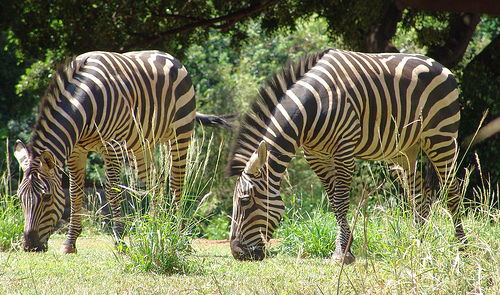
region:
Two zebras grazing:
[23, 75, 454, 256]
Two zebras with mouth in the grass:
[17, 87, 382, 263]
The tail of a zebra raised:
[207, 115, 226, 125]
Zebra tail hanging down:
[426, 170, 435, 187]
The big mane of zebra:
[251, 104, 267, 124]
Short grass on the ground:
[52, 275, 86, 293]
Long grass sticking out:
[140, 230, 173, 269]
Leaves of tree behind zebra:
[72, 22, 124, 46]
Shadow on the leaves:
[472, 71, 497, 103]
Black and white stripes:
[51, 109, 83, 114]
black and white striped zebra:
[7, 35, 201, 245]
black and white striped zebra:
[212, 38, 467, 254]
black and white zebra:
[226, 34, 478, 267]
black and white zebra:
[12, 41, 209, 254]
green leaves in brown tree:
[234, 30, 279, 61]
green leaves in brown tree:
[39, 15, 75, 29]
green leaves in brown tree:
[19, 22, 64, 59]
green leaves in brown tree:
[223, 36, 262, 75]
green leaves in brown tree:
[255, 9, 322, 51]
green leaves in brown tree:
[430, 11, 477, 38]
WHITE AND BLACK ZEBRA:
[27, 58, 168, 240]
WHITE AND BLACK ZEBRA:
[259, 45, 474, 249]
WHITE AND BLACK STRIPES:
[97, 56, 150, 113]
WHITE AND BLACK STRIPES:
[332, 85, 427, 157]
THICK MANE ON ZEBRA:
[239, 60, 294, 137]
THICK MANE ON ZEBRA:
[6, 58, 73, 149]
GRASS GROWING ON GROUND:
[152, 239, 369, 292]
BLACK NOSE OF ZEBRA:
[227, 237, 284, 263]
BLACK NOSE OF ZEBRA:
[22, 228, 57, 263]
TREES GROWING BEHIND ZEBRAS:
[0, 37, 470, 235]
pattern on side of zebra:
[351, 70, 434, 110]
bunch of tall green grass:
[112, 143, 222, 274]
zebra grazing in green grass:
[223, 46, 469, 275]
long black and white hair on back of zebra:
[226, 69, 273, 149]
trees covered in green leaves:
[2, 0, 132, 43]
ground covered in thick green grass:
[16, 255, 115, 294]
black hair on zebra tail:
[193, 108, 243, 138]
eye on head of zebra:
[231, 187, 261, 214]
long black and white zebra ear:
[241, 137, 273, 179]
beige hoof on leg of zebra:
[57, 239, 81, 259]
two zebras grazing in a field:
[12, 48, 469, 263]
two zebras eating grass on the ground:
[13, 46, 469, 264]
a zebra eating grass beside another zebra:
[225, 46, 467, 264]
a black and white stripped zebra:
[13, 48, 197, 255]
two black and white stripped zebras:
[12, 49, 467, 266]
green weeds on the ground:
[91, 108, 223, 276]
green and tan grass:
[1, 253, 109, 294]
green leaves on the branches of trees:
[1, 0, 498, 45]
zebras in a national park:
[11, 45, 468, 265]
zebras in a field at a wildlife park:
[1, 1, 498, 293]